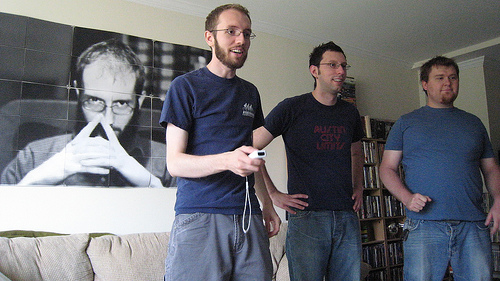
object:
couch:
[0, 217, 297, 281]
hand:
[227, 143, 265, 178]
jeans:
[398, 215, 500, 281]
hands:
[269, 192, 310, 215]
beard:
[212, 39, 249, 70]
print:
[242, 103, 255, 118]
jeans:
[278, 202, 366, 281]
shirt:
[380, 103, 500, 226]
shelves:
[357, 217, 386, 246]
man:
[374, 54, 500, 281]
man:
[246, 37, 374, 281]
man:
[158, 0, 285, 281]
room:
[0, 0, 500, 281]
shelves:
[356, 241, 392, 273]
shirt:
[259, 89, 370, 213]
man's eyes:
[226, 29, 238, 35]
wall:
[0, 0, 424, 234]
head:
[200, 1, 258, 68]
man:
[0, 35, 186, 187]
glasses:
[80, 100, 140, 116]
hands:
[351, 188, 365, 215]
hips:
[279, 192, 363, 221]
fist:
[405, 192, 433, 214]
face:
[209, 6, 258, 70]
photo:
[0, 12, 228, 189]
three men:
[153, 1, 499, 281]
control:
[246, 149, 268, 159]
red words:
[319, 134, 343, 142]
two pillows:
[0, 230, 186, 281]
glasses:
[200, 25, 258, 41]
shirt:
[158, 64, 269, 218]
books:
[369, 166, 377, 189]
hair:
[205, 3, 251, 31]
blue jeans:
[164, 208, 279, 281]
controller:
[247, 149, 268, 158]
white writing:
[243, 102, 255, 112]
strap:
[238, 176, 257, 235]